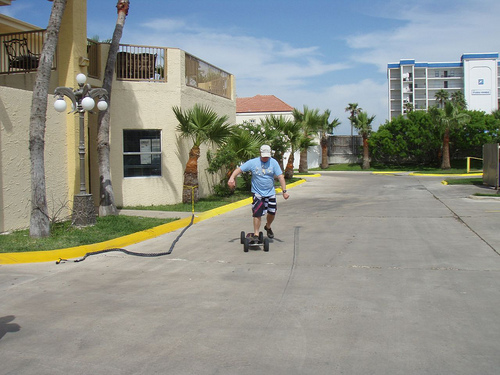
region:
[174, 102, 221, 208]
mini palm tree by house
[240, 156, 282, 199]
blue cotton tee shirt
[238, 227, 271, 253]
black skate board on road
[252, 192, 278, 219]
blue red and grey shorts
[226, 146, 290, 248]
man wearing baseball cap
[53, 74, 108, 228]
grey and white street lamp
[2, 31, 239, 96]
brown wood patio railing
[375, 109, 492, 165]
tree with green leaves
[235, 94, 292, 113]
red shingles on roof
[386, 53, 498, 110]
grey and blue building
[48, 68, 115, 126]
these are white lights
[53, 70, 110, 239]
this is a light pole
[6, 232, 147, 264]
this is a yellow curb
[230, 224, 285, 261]
a skateboard with big wheels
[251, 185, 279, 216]
these are dark blue shorts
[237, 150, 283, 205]
this is a blue shirt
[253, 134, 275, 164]
this is a hat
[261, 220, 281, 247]
this is a left shoe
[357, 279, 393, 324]
this is gray concrete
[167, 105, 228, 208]
this is a tree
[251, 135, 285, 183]
man wearing white cap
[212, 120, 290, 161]
man wearing white cap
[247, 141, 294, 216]
man wearing white cap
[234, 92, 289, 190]
man wearing white cap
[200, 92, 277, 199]
man wearing white cap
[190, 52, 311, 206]
man wearing white cap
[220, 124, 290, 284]
man wearing white cap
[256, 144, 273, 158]
Person wearing white hat.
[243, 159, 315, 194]
Person wearing blue shirt.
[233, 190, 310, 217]
Person wearing shorts.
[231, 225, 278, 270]
Black wheels on board.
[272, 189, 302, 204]
Person wearing watch on wrist.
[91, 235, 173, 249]
Yellow painted curb on side of street.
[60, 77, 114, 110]
Lights on gray post.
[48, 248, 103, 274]
Hose laying in the street.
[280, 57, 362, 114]
White clouds in sky.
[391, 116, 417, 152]
Green leaves on tree.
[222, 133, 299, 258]
a boy on a skateboard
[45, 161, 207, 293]
a water hose by the curb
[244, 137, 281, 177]
a boy wearing a hat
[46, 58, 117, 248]
a out door lamp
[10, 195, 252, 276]
a curb painted yellow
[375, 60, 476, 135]
a white building with several levels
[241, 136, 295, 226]
a boy wearing a blue shirt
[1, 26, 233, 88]
a balcony with patio furniture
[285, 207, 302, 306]
a black skid mark in the road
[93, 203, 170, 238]
a sidewalk